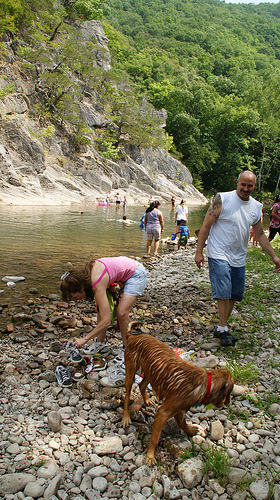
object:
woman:
[58, 255, 148, 357]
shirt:
[92, 255, 141, 288]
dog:
[121, 317, 235, 472]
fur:
[142, 352, 184, 387]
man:
[195, 163, 280, 347]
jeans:
[208, 257, 246, 302]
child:
[171, 218, 192, 250]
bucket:
[171, 231, 177, 241]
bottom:
[0, 177, 209, 204]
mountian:
[0, 0, 280, 201]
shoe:
[64, 341, 83, 364]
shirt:
[205, 190, 265, 267]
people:
[122, 195, 126, 219]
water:
[0, 201, 214, 335]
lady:
[144, 200, 165, 257]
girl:
[175, 199, 189, 233]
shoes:
[54, 363, 73, 390]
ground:
[0, 236, 280, 497]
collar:
[203, 369, 212, 406]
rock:
[0, 466, 31, 498]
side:
[0, 35, 196, 208]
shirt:
[175, 205, 188, 222]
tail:
[126, 320, 146, 343]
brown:
[164, 395, 176, 413]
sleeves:
[214, 192, 223, 216]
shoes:
[214, 328, 232, 347]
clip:
[61, 269, 71, 282]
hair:
[60, 261, 96, 305]